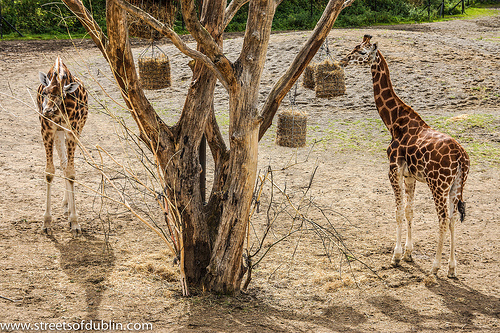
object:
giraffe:
[35, 55, 90, 237]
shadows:
[43, 222, 117, 333]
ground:
[11, 39, 499, 332]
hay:
[139, 62, 170, 81]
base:
[176, 277, 254, 301]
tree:
[55, 0, 356, 295]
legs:
[40, 119, 88, 239]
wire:
[135, 31, 170, 59]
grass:
[42, 32, 63, 42]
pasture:
[0, 0, 500, 333]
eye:
[358, 52, 367, 57]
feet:
[41, 213, 86, 238]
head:
[337, 34, 379, 69]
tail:
[457, 158, 469, 225]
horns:
[361, 34, 373, 45]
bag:
[301, 60, 348, 101]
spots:
[359, 31, 468, 67]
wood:
[109, 1, 122, 18]